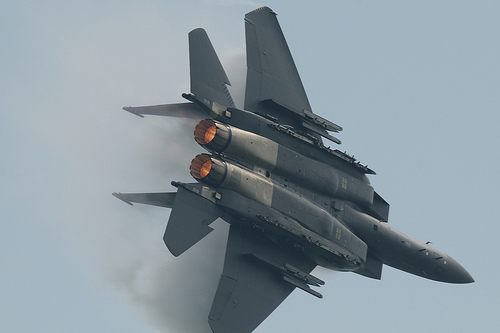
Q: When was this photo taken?
A: During the daytime.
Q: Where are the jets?
A: In the back of the plane.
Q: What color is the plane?
A: Gray.